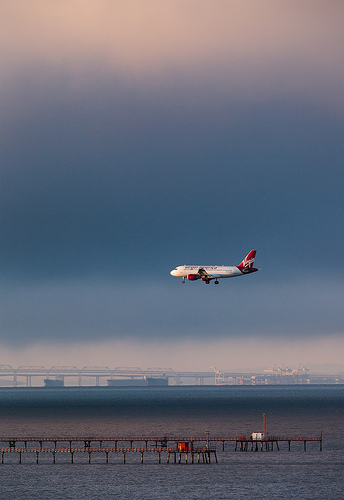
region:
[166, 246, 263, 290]
Plane in the air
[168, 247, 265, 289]
Plane is in the air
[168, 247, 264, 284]
Airplane in the air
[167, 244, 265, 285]
Airplane is in the air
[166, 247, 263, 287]
Plane flying in the air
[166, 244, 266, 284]
Plane is flying in the air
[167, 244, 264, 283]
Airplane flying in the air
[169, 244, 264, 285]
Airplane is flying in the air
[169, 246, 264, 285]
Red and white plane in the air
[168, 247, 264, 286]
Red and white airplane in the air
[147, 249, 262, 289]
red and white plane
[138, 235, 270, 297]
plane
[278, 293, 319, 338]
white clouds in blue sky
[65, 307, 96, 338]
white clouds in blue sky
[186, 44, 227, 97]
white clouds in blue sky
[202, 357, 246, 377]
white clouds in blue sky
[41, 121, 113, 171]
white clouds in blue sky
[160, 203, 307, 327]
an airplane in the air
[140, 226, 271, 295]
a plane in the air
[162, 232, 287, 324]
an airplane in the sky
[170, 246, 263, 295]
a large airplane in the air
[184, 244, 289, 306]
a large plane in the air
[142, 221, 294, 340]
a large airplane in the sky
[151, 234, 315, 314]
a large plane in the sky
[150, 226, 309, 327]
a passenger plane in the air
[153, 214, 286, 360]
a large airplane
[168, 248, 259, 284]
Airplane in the air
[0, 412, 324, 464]
Pier on the water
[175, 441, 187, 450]
Red shack on the pier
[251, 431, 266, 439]
White shack on the pier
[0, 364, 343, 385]
Bridge over the water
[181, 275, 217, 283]
Landing gear down on the plane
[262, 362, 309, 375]
Plant behind the bridge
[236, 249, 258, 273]
Virgin Air logo on red tail of airplane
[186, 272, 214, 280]
Red jet engines on the airplane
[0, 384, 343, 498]
Water with small waves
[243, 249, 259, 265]
red and white wing on plane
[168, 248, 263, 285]
red and white plane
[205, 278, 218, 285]
black wheels on plane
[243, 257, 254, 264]
white stripe on plane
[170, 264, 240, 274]
white body of plane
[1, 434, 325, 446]
long pier on water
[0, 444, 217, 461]
long pier on water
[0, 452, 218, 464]
wooden posts on pier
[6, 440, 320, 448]
wooden posts on pier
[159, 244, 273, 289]
Virgin airlines passenger jet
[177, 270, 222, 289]
deployed passenger jet landing wheels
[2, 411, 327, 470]
two large docks in water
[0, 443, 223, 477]
smaller dock near in the water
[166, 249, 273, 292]
passenger jet on it's way to land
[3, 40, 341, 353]
massive hazy cloud in sky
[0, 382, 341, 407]
large wall in the ocean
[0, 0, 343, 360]
dark blue and cloudy weather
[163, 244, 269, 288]
an airplane in flight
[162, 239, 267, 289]
a virgin jet plane in flight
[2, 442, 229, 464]
a red pier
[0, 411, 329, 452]
a red pier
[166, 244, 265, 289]
a plane with a red tail fin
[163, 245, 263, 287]
a plane with its landing gear down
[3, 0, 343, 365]
a bleak and empty sky